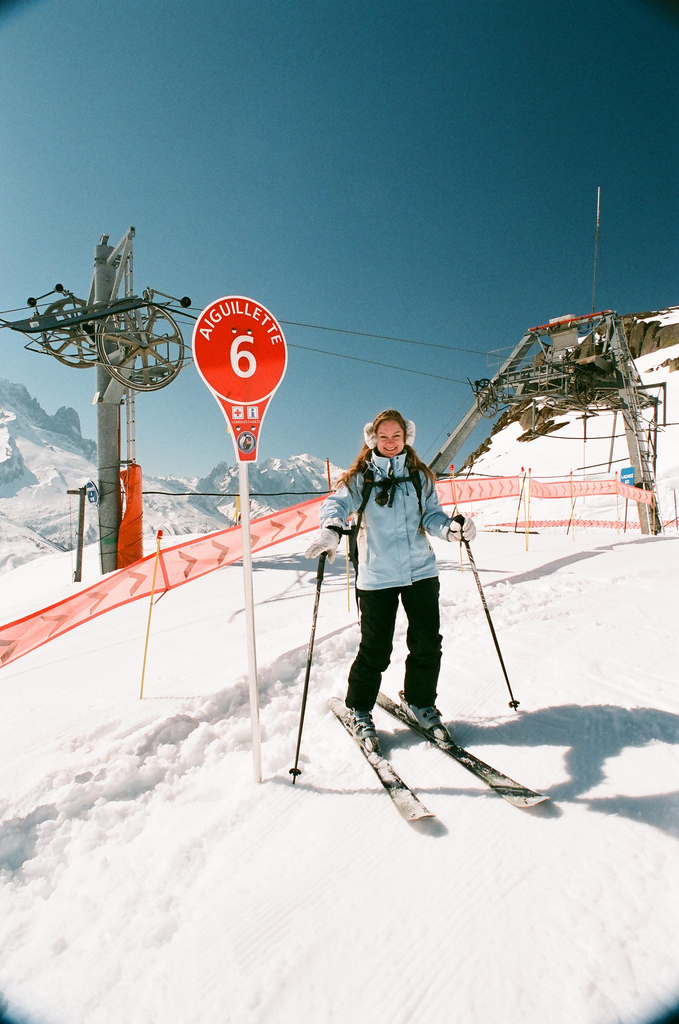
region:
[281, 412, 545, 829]
A woman standing on skis.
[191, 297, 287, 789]
A red and white sign .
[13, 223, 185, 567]
A ski left pulleys .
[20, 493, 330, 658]
A orange mesh border.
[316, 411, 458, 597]
A lady in a blue jacket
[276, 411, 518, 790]
A lady holding ski poles.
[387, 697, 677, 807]
A skiers shadow on the snow.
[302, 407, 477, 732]
A lady wearing ear muffs.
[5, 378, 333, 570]
Snow covered mountains in the distance.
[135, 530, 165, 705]
A yellow and orange pole.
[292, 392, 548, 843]
woman skiing in white snow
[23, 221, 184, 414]
gray ski lift machinery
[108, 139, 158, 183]
blue sky with no clouds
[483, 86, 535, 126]
blue sky with no clouds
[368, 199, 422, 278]
blue sky with no clouds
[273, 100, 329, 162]
blue sky with no clouds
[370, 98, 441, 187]
blue sky with no clouds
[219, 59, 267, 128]
blue sky with no clouds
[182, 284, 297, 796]
the sign is red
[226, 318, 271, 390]
number 6 on a sign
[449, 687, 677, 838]
shadow on the snow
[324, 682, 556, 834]
skies on the snow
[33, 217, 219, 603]
a pole on the snow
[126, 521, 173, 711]
teh stick is color yellow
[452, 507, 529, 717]
the pole is black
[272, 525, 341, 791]
the pole is black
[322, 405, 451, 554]
the hair is long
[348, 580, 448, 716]
the pants are black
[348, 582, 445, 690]
woman wearing black pants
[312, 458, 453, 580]
woman wearing a blue jacket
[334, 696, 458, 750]
woman wearing ski boots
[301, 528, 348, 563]
woman wearing white gloves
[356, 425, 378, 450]
woman wearing ear muffs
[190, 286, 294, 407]
number 6 on the pole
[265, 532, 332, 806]
woman holding a ski pole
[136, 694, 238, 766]
foot prints in the snow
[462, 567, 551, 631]
foot prints in the snow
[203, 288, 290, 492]
red and white sign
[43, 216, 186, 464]
gray machinery of ski lift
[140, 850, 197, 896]
white snow on hill side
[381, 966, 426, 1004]
white snow on hill side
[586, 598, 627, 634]
white snow on hill side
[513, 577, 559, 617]
white snow on hill side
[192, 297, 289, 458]
red and white sign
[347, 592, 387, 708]
leg of a woman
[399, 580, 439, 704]
leg of a woman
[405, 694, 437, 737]
foot of a woman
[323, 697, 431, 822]
snow on the ski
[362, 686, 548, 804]
snow on the ski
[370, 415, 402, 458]
face of a woman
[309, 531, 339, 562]
the glove is white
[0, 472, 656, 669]
the barrier is orange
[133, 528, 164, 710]
yellow pole sticking out of the snow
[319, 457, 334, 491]
yellow pole sticking out of the snow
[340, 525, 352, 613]
yellow pole sticking out of the snow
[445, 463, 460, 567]
yellow pole sticking out of the snow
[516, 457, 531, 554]
yellow pole sticking out of the snow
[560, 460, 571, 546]
yellow pole sticking out of the snow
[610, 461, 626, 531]
yellow pole sticking out of the snow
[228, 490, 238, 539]
yellow pole sticking out of the snow